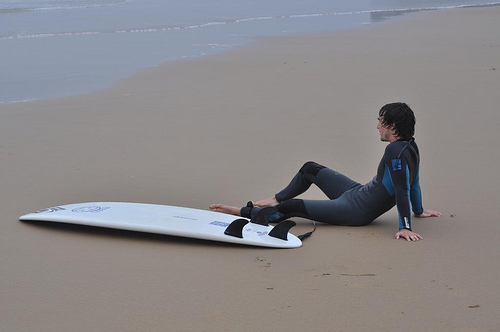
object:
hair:
[379, 102, 415, 140]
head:
[377, 102, 416, 143]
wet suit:
[239, 137, 423, 231]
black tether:
[224, 206, 297, 241]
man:
[209, 102, 442, 242]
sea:
[0, 0, 500, 105]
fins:
[268, 220, 297, 241]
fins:
[224, 219, 248, 238]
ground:
[320, 246, 500, 331]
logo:
[71, 206, 111, 214]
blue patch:
[391, 159, 402, 171]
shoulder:
[388, 141, 408, 154]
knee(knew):
[303, 160, 320, 171]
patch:
[299, 161, 328, 177]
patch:
[276, 199, 309, 216]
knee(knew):
[282, 198, 305, 213]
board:
[18, 201, 304, 249]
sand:
[0, 6, 500, 332]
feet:
[209, 203, 254, 217]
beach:
[0, 5, 500, 332]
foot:
[249, 196, 282, 207]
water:
[0, 0, 500, 108]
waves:
[3, 2, 499, 44]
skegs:
[224, 207, 297, 241]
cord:
[298, 221, 317, 241]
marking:
[32, 206, 112, 213]